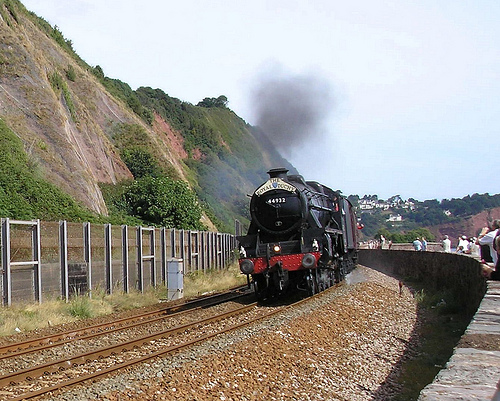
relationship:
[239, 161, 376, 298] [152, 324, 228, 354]
train on tracks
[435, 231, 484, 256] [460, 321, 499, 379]
people are on walkway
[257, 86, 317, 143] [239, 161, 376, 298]
smoke above train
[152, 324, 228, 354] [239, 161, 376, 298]
tracks in front of train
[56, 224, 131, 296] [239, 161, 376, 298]
barrier next to train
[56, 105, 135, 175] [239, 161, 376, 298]
hill next to train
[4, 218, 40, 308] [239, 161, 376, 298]
wall next to train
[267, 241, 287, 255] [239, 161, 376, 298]
headlight of train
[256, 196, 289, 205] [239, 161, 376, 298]
number on train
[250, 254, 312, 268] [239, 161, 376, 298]
plate on train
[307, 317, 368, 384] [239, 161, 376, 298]
slope next to train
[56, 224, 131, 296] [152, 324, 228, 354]
barrier next to tracks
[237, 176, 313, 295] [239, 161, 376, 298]
front of train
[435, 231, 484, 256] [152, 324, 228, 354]
people next to tracks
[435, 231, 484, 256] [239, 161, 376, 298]
people watching train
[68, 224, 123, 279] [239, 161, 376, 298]
barrier next to train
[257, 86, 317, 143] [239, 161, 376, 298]
smoke from train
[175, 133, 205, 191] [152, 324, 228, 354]
cliff next to tracks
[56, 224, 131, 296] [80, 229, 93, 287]
barrier with post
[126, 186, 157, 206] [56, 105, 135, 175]
bushes on hill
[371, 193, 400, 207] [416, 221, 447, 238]
buildings on hill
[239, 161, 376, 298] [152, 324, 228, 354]
train moving on tracks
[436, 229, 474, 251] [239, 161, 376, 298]
crowd watches train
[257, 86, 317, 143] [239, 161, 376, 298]
smoke rises from train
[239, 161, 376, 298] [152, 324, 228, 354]
engine on tracks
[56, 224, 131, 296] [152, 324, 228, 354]
barrier behind tracks